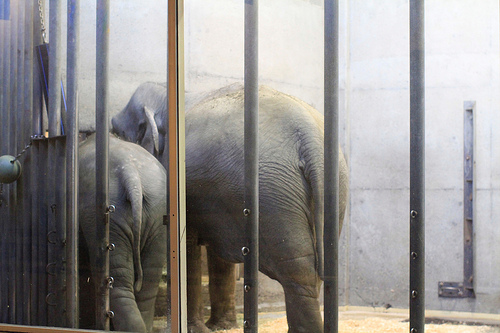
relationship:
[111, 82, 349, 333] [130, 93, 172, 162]
elephant has an ear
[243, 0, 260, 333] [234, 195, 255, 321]
bar has rings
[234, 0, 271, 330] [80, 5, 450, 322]
metal pole of fence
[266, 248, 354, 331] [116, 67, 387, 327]
leg of elephant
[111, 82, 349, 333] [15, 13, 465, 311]
elephant in cage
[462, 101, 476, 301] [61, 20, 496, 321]
bar on wall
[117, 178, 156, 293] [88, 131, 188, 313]
tail attached to elephant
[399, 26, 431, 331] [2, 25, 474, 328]
pole attached to fence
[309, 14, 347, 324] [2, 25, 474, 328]
pole attached to fence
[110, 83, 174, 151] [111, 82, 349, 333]
head attached to elephant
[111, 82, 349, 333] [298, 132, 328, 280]
elephant has tail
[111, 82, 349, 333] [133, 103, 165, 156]
elephant has ear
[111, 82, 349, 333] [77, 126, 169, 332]
elephant standing next to elephant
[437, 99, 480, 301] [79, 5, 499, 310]
bar on wall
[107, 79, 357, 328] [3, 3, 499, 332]
elephant in cage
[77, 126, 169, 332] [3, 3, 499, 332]
elephant in cage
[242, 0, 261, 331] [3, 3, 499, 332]
bar on cage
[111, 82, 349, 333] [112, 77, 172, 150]
elephant has head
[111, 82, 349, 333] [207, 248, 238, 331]
elephant has leg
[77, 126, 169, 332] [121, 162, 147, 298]
elephant has tail